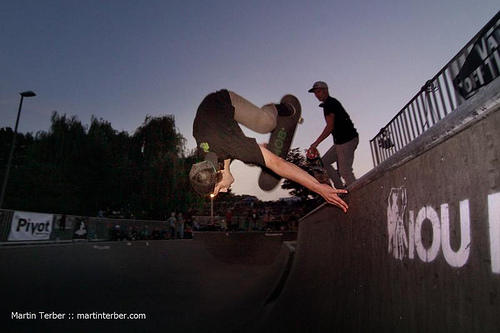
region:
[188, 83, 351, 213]
skateboarder is upside down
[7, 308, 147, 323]
white signature and website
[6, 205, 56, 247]
white banner with black letters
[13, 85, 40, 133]
black street lamp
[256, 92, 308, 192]
skateboard by the upside down skateboarder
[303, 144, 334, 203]
skateboard in the standing skateboarder's hand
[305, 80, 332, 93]
hat on the standing skateboarder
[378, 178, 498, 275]
white logo on the quarter pipe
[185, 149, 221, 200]
hat on the upside down skateboarder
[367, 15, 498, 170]
metal fence at the skatepark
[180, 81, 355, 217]
this skateboard dude is performing a trick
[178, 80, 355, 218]
skateboard dude flying through midair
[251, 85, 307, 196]
the dude's skateboard is completely vertical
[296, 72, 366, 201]
another skateboard dude watches in awe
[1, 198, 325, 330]
these curved ramps enable skateboard dudes to show their stuff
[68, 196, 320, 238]
spectators watch skateboard dude perform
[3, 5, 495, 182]
the sun has set and it's getting dark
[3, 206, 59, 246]
Pivot is a sponsor of this event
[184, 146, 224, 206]
skateboard dude is wearing a cap on backwards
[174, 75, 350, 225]
Man in the air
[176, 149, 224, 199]
Hat on the man's head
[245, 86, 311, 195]
Skateboard under the man's feet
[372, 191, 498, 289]
White letters on the ramp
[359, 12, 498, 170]
Rail on top of ramp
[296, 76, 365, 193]
Man wearing a black shirt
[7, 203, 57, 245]
Sign in the background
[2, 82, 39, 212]
Lamp in the background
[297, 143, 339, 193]
Skateboard in the man's hand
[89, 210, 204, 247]
People in the background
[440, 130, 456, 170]
part of a board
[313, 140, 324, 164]
part of a board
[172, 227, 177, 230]
part of a rail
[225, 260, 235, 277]
part of a finger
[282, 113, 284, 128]
edge of a board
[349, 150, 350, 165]
part of a trouser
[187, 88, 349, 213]
A boy on a skateboard.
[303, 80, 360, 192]
A boy holding a skateboard.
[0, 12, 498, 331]
A skate park in a park.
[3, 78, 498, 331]
Cement skateboard ramps.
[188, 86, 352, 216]
A boy in the air.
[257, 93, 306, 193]
A skateboard in the air.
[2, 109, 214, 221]
Trees by a skate park.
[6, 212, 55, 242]
A banner on a fence.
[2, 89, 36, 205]
A light in the park.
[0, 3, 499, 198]
A clear blue sky.